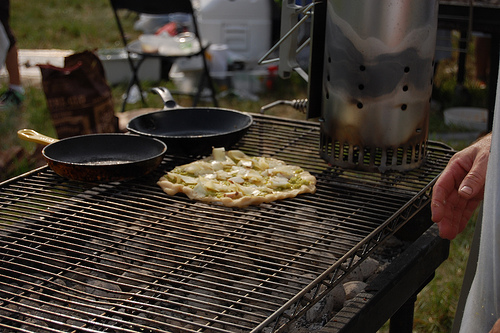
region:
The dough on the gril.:
[159, 143, 331, 210]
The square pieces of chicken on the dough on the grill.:
[185, 146, 292, 195]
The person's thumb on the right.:
[464, 158, 481, 200]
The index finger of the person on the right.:
[426, 157, 458, 220]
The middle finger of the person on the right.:
[443, 183, 460, 243]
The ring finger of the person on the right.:
[453, 192, 463, 237]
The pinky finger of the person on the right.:
[464, 191, 479, 236]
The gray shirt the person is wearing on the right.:
[469, 72, 499, 332]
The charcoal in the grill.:
[54, 224, 416, 325]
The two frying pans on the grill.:
[19, 92, 254, 186]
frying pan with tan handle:
[28, 117, 141, 190]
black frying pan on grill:
[133, 71, 236, 148]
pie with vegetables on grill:
[149, 157, 329, 221]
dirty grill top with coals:
[37, 222, 285, 292]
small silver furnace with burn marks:
[307, 39, 451, 196]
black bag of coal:
[36, 39, 142, 116]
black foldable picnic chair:
[105, 0, 227, 103]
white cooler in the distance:
[210, 0, 266, 91]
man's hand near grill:
[437, 112, 498, 234]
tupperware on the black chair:
[136, 18, 206, 60]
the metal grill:
[32, 105, 399, 321]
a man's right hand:
[429, 128, 486, 240]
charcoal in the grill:
[88, 229, 302, 331]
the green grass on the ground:
[397, 238, 468, 332]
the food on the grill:
[155, 148, 322, 207]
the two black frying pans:
[22, 79, 250, 178]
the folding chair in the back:
[103, 0, 223, 112]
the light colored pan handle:
[13, 128, 58, 145]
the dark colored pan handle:
[147, 81, 180, 111]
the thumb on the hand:
[460, 153, 488, 200]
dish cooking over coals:
[159, 148, 321, 208]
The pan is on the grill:
[14, 117, 167, 179]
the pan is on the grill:
[122, 83, 264, 152]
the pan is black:
[120, 76, 260, 142]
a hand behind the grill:
[427, 99, 496, 237]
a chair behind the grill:
[105, 2, 235, 106]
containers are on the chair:
[128, 23, 200, 57]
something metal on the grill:
[253, 2, 451, 204]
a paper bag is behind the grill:
[37, 48, 124, 140]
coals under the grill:
[27, 193, 402, 325]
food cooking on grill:
[167, 144, 318, 210]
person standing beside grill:
[428, 41, 498, 327]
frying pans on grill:
[11, 87, 263, 177]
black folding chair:
[106, 2, 230, 108]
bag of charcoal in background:
[31, 51, 118, 133]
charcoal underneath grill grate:
[7, 172, 383, 329]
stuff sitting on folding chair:
[127, 27, 199, 63]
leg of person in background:
[4, 2, 31, 107]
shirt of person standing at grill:
[455, 52, 498, 332]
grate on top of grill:
[1, 96, 451, 332]